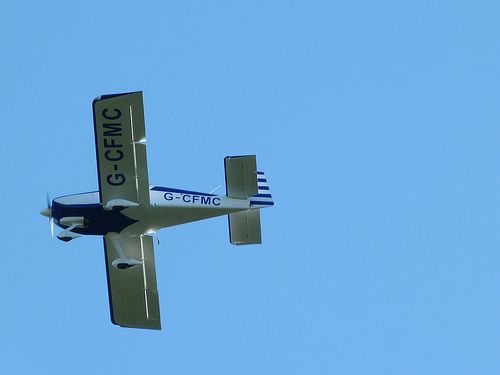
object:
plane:
[40, 91, 276, 330]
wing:
[92, 90, 148, 209]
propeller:
[50, 216, 55, 238]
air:
[290, 95, 454, 317]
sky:
[0, 0, 500, 375]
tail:
[248, 171, 275, 210]